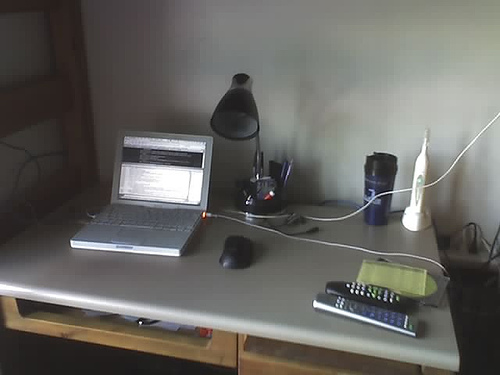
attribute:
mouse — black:
[215, 233, 257, 269]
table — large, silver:
[22, 156, 453, 342]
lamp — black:
[221, 72, 281, 212]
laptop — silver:
[78, 131, 252, 275]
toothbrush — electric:
[407, 127, 430, 208]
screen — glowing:
[118, 137, 209, 206]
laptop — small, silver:
[85, 115, 232, 293]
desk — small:
[5, 179, 496, 369]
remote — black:
[324, 280, 416, 313]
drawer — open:
[7, 288, 230, 369]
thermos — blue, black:
[359, 133, 389, 225]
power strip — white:
[438, 227, 498, 267]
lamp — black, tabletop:
[210, 50, 278, 235]